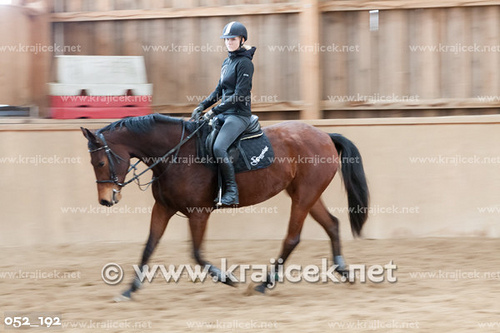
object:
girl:
[188, 19, 255, 206]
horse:
[80, 111, 372, 299]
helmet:
[220, 22, 249, 39]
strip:
[238, 36, 243, 49]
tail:
[327, 131, 369, 238]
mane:
[91, 114, 193, 134]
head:
[78, 124, 133, 207]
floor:
[3, 115, 498, 331]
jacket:
[201, 46, 256, 115]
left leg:
[211, 115, 248, 207]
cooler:
[47, 53, 157, 119]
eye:
[94, 158, 105, 166]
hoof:
[118, 285, 136, 300]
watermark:
[99, 257, 397, 285]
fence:
[30, 2, 498, 117]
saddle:
[188, 108, 264, 159]